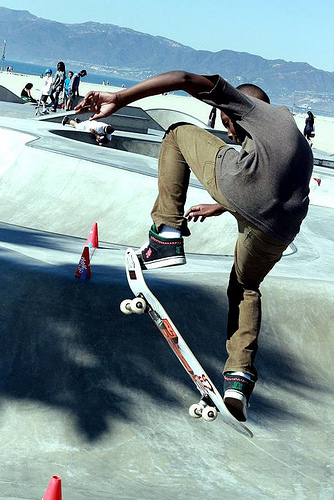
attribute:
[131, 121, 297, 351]
jeans — olive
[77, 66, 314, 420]
boy — dark skinned, young, black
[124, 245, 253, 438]
skateboard — skate, white , printed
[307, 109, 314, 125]
hair — long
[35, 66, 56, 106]
skater — young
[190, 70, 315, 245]
shirt — gray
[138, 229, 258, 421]
shoes — black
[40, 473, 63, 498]
cone — red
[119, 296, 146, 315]
wheels — white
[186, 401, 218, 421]
wheels — white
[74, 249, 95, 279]
cone — orange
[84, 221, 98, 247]
cone — orange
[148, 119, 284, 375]
pants — brown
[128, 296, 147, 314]
wheel — white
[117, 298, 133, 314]
wheel — white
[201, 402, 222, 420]
wheel — white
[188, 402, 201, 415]
wheel — white